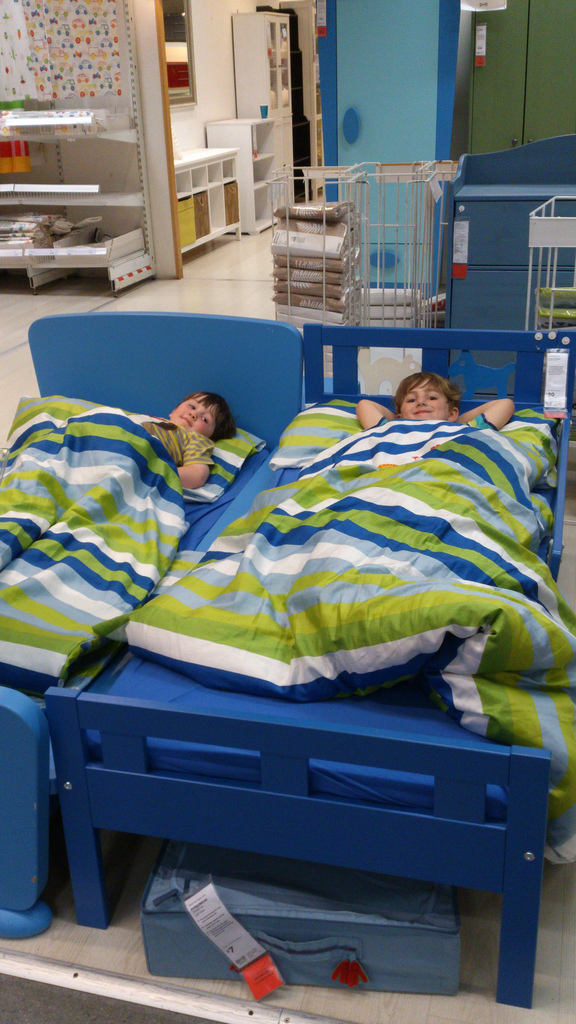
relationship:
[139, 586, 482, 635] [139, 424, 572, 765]
stripe on blanket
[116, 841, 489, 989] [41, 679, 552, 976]
storage container underneath bed frame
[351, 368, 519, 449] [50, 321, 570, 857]
boy laying on a bed bed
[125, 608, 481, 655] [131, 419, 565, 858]
stripe on blanket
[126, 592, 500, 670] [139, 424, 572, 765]
stripe on blanket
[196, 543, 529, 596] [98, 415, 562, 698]
stripe on blanket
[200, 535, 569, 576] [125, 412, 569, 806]
stripe on blanket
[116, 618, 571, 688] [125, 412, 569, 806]
stripe on blanket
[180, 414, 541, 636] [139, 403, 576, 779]
stripes on blanket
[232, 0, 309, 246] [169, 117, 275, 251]
cabinets on shelves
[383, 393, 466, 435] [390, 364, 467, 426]
hands behind head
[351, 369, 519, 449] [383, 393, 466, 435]
boy has hands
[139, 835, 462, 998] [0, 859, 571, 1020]
storage container on floor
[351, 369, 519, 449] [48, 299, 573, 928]
boy laying bed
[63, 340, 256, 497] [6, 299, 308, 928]
boy laying bed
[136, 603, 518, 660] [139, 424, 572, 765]
stripe on blanket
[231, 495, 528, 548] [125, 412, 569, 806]
stripe on blanket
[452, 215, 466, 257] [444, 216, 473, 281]
printing on label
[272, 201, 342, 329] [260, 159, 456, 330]
linens on racks